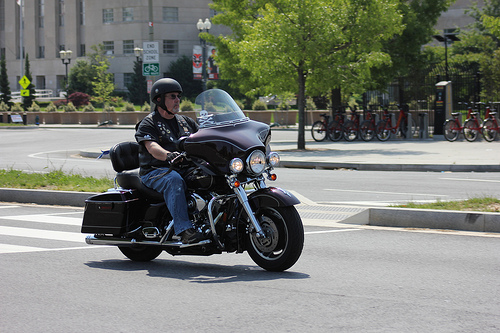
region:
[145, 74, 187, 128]
head of a person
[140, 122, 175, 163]
arm of a person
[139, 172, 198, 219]
leg of a person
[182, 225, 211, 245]
feet of a person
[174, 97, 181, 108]
nose of a person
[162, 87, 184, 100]
eye of a person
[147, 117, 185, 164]
an arm of a person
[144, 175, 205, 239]
a leg of a person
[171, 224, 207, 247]
a feet of a person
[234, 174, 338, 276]
wheel of a bike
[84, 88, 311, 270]
man riding on motorcycle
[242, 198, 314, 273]
front black wheel of motorcycle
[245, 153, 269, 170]
white light on front of bike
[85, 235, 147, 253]
silver muffler on bike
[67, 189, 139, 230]
black carrying case on bike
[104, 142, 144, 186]
black seat on bike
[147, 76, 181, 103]
black helmet on bike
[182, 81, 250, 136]
front windshield on bike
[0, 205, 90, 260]
part of a white crosswalk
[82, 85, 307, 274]
a large motorcycle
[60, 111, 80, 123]
a large brown planter container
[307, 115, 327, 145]
a bike tire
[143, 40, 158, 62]
a black and white street sign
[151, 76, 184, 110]
a black helmet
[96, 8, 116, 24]
a window of a building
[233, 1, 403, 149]
a large green tree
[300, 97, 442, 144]
bicycles in a rack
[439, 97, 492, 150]
bicycles in a rack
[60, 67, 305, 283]
man on a motorcycle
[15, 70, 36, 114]
cross walk sign by road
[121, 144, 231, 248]
person wearing blue jeans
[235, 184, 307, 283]
wheel on a motorcycle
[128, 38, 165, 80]
end school zone sign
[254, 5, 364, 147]
green leaves on tree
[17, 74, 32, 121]
two neon signs on pole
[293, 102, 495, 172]
bikes parked on sidewalk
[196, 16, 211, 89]
street lights on pole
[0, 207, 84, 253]
white block lines on street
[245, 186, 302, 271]
fender over bike tire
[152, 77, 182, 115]
black helmet on head